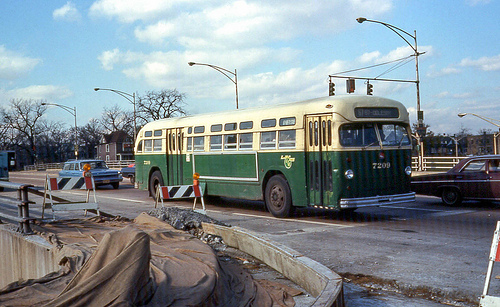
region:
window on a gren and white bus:
[276, 122, 301, 152]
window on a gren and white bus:
[257, 128, 277, 150]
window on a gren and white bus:
[237, 128, 255, 151]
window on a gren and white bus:
[222, 129, 238, 151]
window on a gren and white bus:
[207, 130, 222, 152]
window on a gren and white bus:
[340, 119, 414, 149]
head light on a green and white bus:
[342, 167, 356, 182]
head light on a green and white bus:
[401, 164, 415, 177]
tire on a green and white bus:
[258, 170, 293, 220]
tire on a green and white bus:
[144, 167, 165, 200]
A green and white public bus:
[118, 87, 421, 227]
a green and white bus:
[135, 95, 414, 204]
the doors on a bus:
[292, 115, 339, 203]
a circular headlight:
[342, 164, 356, 181]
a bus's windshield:
[331, 105, 413, 152]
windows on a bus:
[138, 118, 300, 158]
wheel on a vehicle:
[261, 176, 293, 211]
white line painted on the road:
[222, 203, 355, 241]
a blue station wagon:
[58, 154, 121, 189]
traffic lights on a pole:
[325, 72, 383, 96]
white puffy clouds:
[67, 3, 288, 55]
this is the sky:
[25, 21, 85, 76]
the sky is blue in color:
[59, 30, 88, 75]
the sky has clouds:
[157, 18, 256, 69]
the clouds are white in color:
[203, 24, 250, 47]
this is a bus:
[131, 109, 417, 199]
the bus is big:
[157, 108, 401, 213]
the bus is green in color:
[230, 164, 259, 196]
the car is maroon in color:
[460, 179, 472, 186]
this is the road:
[393, 222, 448, 274]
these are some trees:
[22, 117, 86, 167]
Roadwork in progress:
[1, 179, 376, 302]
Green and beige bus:
[123, 93, 433, 213]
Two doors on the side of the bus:
[155, 106, 335, 214]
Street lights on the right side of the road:
[36, 11, 446, 203]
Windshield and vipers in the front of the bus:
[338, 117, 418, 154]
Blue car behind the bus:
[58, 155, 123, 187]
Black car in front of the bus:
[408, 148, 498, 198]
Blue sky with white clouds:
[5, 4, 490, 129]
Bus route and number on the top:
[352, 100, 404, 120]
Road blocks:
[41, 168, 227, 215]